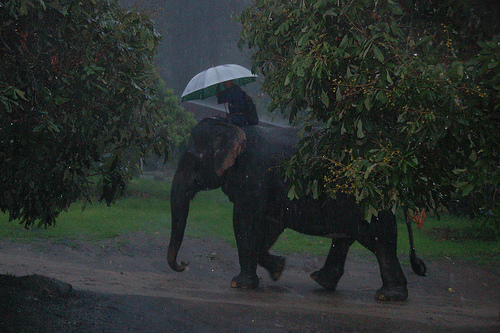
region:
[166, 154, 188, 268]
the trunk of an elephant walking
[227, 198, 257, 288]
the leg of an elephant walking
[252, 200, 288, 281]
the leg of an elephant walking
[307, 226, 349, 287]
the leg of an elephant walking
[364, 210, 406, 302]
the leg of an elephant walking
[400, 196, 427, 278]
the tail of an elephant walking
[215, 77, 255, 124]
a person sitting on an elephant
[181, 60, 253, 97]
a large green umbrella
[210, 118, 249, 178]
the ear of an elephant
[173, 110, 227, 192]
the head of an elephant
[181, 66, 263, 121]
the person is on an elephant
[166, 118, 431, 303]
the elephant is wet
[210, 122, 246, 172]
the elephant has brown ears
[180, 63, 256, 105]
the person holds an umbrella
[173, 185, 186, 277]
the elephant has a long trunk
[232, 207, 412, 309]
the elephant has four legs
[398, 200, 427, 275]
the elephant has a long tail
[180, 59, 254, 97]
the umbrella is blue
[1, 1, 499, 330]
it is raining outdoors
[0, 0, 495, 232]
the trees have leaves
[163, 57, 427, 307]
a person riding an elephant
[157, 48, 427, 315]
a person riding an elephant in the rain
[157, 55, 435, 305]
a person and an elephant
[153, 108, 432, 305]
an elephant in the rain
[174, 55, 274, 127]
a person in the rain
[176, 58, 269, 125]
a person holding an umbrella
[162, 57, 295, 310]
a person on top of an elephant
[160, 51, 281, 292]
a person riding on top of an elephant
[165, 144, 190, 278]
the trunk of an elephant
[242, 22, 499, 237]
leaves on a tree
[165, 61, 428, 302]
Person riding on the back of an elephant.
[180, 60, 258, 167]
The person is holding a white umbrella.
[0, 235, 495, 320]
The elephant is walking on a dirt path.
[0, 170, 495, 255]
Green grass next to the path.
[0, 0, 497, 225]
Tree limbs hanging over the path.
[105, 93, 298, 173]
A building near the path.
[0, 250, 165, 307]
A puddle of muddy water on the path.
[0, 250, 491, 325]
A stream of muddy water on the path.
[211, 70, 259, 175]
Person sitting near the elephant's head.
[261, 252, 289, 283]
Hoof of the elephant lifted off of the ground.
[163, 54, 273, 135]
this driver is wearing an umbrella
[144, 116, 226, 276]
the elephant has a long trunk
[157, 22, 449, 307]
the rain is pouring down in the area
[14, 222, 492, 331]
a muddy pathway for the elephant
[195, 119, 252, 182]
the elephant has a big ear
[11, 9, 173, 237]
the trees in the area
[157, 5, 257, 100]
a light blue umbrella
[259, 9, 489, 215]
a lot of leaves on the tree